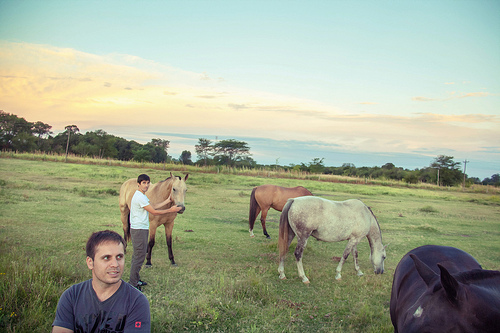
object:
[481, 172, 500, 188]
foliage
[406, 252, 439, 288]
ear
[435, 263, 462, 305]
ear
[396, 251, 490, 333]
head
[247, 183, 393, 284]
two horses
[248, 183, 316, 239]
brown horse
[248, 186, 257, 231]
tail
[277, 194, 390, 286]
white/gray horse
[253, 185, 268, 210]
backside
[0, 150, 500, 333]
field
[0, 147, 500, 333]
grass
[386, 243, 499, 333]
horse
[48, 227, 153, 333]
man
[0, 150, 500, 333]
ground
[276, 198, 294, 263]
hair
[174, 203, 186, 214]
snout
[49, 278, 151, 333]
shirt